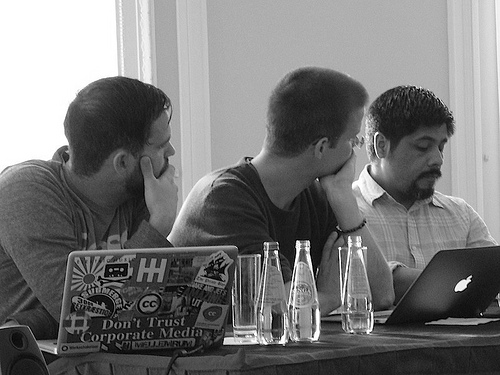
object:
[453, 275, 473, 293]
logo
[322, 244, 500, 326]
laptop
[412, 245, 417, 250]
button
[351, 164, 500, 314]
shirt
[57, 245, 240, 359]
back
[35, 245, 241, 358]
laptop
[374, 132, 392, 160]
ear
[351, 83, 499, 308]
man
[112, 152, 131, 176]
ear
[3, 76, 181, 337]
man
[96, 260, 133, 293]
sticker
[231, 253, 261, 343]
glass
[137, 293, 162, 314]
sticker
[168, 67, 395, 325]
man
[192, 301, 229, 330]
sticker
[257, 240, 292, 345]
bottle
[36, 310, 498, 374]
table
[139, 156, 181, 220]
hand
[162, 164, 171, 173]
mouth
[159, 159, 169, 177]
mustache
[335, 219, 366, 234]
band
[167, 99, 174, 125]
hair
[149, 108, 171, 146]
forehead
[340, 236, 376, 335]
glass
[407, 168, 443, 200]
beard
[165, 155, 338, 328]
shirt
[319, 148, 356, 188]
hand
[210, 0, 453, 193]
wall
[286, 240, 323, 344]
bottle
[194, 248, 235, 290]
sticker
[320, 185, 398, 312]
arm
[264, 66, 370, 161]
hair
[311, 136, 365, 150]
glasses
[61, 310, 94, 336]
sticker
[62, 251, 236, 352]
sticker